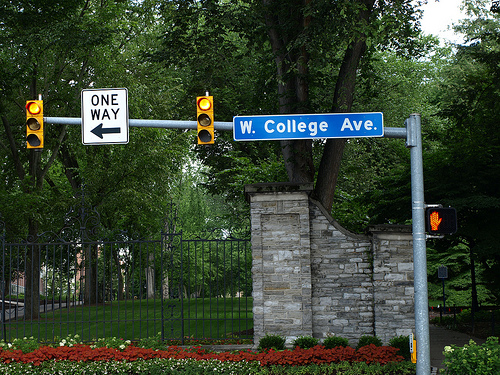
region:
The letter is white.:
[237, 119, 253, 135]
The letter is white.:
[260, 114, 277, 135]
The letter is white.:
[275, 120, 286, 135]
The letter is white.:
[283, 115, 292, 135]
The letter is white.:
[289, 116, 299, 137]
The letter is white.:
[295, 119, 307, 135]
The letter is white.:
[306, 118, 321, 140]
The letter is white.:
[318, 117, 331, 137]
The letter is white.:
[337, 113, 354, 135]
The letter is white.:
[351, 115, 363, 135]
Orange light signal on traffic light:
[195, 98, 212, 111]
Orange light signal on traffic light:
[26, 101, 40, 116]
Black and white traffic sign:
[79, 88, 129, 144]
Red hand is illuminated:
[425, 208, 444, 233]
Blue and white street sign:
[231, 113, 386, 141]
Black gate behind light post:
[0, 188, 252, 343]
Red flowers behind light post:
[0, 343, 407, 366]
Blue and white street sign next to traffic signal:
[232, 112, 382, 141]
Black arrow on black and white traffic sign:
[89, 121, 124, 140]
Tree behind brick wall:
[178, 0, 430, 218]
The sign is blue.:
[229, 110, 386, 142]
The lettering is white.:
[230, 113, 386, 141]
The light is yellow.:
[190, 91, 211, 112]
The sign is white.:
[73, 82, 132, 146]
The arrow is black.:
[89, 120, 124, 140]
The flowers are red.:
[7, 343, 408, 363]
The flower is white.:
[440, 341, 457, 355]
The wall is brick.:
[250, 197, 408, 341]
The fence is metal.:
[8, 236, 251, 348]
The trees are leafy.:
[8, 5, 496, 267]